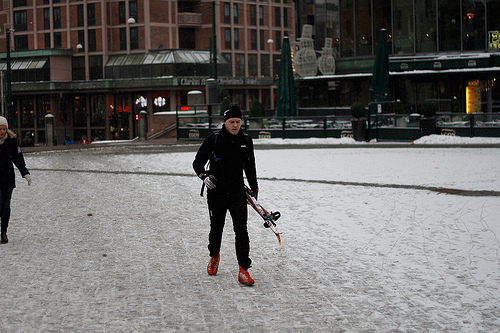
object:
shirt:
[189, 130, 268, 203]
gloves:
[199, 172, 219, 190]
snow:
[0, 135, 498, 331]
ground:
[0, 131, 498, 331]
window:
[258, 29, 266, 51]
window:
[128, 26, 139, 52]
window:
[85, 25, 97, 52]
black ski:
[242, 185, 286, 247]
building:
[0, 0, 296, 147]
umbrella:
[267, 31, 303, 136]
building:
[271, 1, 497, 141]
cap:
[1, 112, 10, 128]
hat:
[222, 104, 244, 122]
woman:
[0, 114, 33, 241]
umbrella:
[369, 21, 394, 114]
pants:
[205, 189, 252, 269]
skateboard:
[238, 178, 286, 246]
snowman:
[316, 30, 337, 78]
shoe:
[205, 252, 221, 276]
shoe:
[236, 263, 256, 287]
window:
[221, 26, 231, 50]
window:
[272, 6, 283, 26]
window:
[282, 7, 293, 27]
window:
[232, 27, 240, 51]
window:
[249, 29, 259, 52]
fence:
[174, 103, 417, 140]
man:
[191, 108, 262, 288]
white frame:
[0, 0, 303, 146]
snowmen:
[293, 18, 318, 78]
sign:
[179, 105, 191, 112]